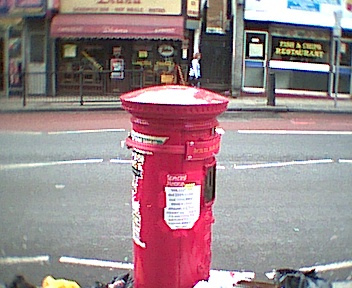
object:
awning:
[51, 13, 186, 41]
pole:
[334, 37, 340, 106]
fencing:
[22, 68, 144, 105]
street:
[0, 109, 351, 285]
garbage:
[40, 275, 80, 288]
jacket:
[188, 59, 201, 76]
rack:
[22, 70, 27, 106]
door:
[24, 31, 55, 95]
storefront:
[52, 0, 184, 98]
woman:
[187, 51, 203, 87]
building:
[54, 0, 187, 99]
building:
[231, 0, 351, 100]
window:
[30, 35, 44, 64]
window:
[270, 35, 330, 62]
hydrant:
[116, 83, 229, 288]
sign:
[249, 43, 264, 58]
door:
[241, 29, 270, 93]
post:
[266, 72, 276, 106]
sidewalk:
[1, 95, 351, 112]